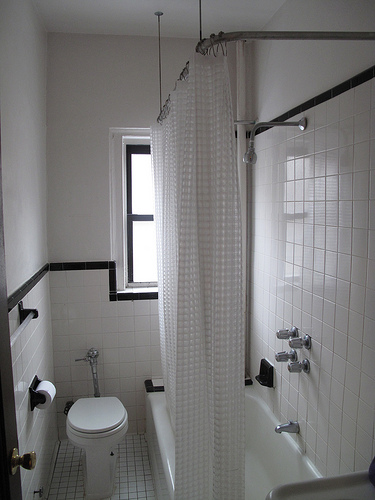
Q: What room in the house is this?
A: Bathroom.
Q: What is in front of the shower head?
A: Curtain.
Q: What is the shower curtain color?
A: White.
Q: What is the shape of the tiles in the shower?
A: Square.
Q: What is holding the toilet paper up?
A: Toilet paper holder.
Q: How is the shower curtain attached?
A: Rod.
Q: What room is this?
A: The bathroom.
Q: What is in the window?
A: Nothing.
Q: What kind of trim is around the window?
A: Wooden trim.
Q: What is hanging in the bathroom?
A: A shower curtain.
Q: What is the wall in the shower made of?
A: Tile.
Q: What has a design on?
A: The shower curtain.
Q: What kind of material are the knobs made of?
A: Chrome.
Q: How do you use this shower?
A: Turn the knobs.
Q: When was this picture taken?
A: Daytime.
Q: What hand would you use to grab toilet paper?
A: Right hand.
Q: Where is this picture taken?
A: Bathroom.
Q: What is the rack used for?
A: To hang towels.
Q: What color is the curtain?
A: White.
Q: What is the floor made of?
A: Tile.